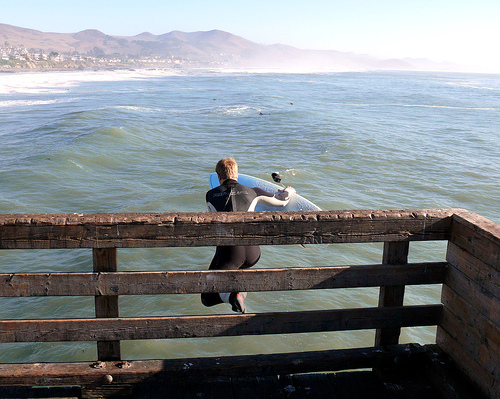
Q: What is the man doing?
A: Jumping into water.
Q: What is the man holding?
A: Surf board.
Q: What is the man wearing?
A: Wet suit.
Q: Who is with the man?
A: No one.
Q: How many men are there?
A: One.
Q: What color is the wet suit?
A: Black.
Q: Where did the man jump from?
A: Pier.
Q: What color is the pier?
A: Brown.